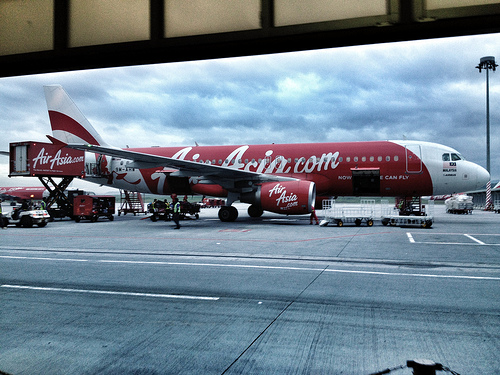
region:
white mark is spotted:
[259, 291, 266, 313]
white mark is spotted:
[252, 292, 263, 310]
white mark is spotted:
[253, 294, 266, 324]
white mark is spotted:
[253, 283, 273, 325]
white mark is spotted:
[247, 278, 264, 310]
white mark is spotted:
[253, 293, 260, 301]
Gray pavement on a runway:
[43, 237, 340, 349]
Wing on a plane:
[61, 114, 315, 206]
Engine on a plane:
[255, 170, 332, 221]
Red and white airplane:
[44, 138, 465, 219]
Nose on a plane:
[421, 133, 496, 200]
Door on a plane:
[395, 137, 425, 188]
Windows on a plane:
[196, 144, 416, 168]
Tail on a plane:
[41, 74, 107, 185]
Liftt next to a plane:
[6, 138, 109, 190]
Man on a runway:
[162, 191, 195, 223]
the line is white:
[156, 288, 163, 296]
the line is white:
[164, 283, 178, 310]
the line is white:
[158, 277, 169, 307]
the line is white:
[147, 285, 166, 304]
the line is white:
[178, 300, 183, 302]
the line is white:
[151, 283, 171, 310]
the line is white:
[180, 291, 187, 307]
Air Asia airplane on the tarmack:
[4, 72, 499, 255]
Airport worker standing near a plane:
[155, 182, 186, 232]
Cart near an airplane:
[301, 185, 446, 230]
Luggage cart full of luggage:
[53, 175, 139, 252]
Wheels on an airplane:
[214, 183, 274, 244]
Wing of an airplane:
[36, 80, 332, 213]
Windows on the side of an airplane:
[187, 147, 409, 173]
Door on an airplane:
[394, 122, 443, 207]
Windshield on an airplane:
[432, 132, 493, 228]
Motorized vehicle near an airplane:
[2, 187, 60, 238]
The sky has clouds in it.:
[205, 70, 387, 127]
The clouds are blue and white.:
[211, 67, 421, 126]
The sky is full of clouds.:
[161, 72, 419, 124]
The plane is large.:
[13, 80, 497, 219]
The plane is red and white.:
[17, 80, 496, 220]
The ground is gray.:
[326, 282, 461, 345]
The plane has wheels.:
[208, 191, 442, 239]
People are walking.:
[148, 187, 204, 236]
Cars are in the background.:
[2, 186, 124, 240]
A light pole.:
[462, 46, 497, 216]